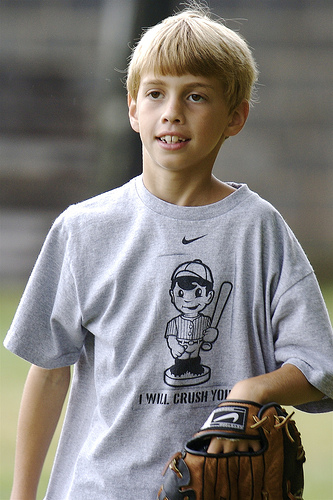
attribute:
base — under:
[162, 366, 210, 387]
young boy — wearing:
[68, 9, 300, 380]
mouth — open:
[154, 128, 202, 149]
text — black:
[138, 385, 233, 405]